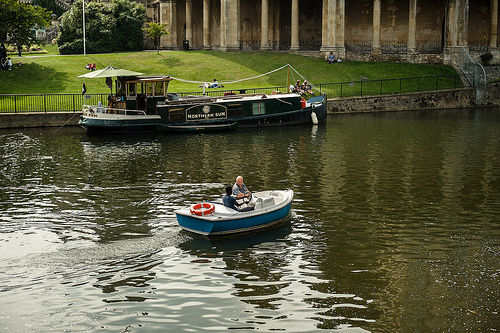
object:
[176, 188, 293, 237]
boat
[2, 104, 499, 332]
river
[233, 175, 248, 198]
tourist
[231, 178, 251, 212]
passenger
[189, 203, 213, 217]
lifesaver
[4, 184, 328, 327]
wake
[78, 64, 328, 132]
boat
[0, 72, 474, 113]
fencing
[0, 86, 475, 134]
wall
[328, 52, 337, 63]
person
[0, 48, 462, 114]
grass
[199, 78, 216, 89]
person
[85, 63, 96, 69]
person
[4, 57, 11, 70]
person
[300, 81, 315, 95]
person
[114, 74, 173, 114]
cabin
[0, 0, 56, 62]
trees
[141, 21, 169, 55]
trees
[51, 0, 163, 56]
trees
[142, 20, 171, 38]
leaves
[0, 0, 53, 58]
leaves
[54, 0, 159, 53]
leaves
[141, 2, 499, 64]
ruin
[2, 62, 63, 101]
shade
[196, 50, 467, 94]
shade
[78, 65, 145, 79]
umbrella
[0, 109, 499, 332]
reflection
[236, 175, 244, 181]
hair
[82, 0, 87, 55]
flag pole